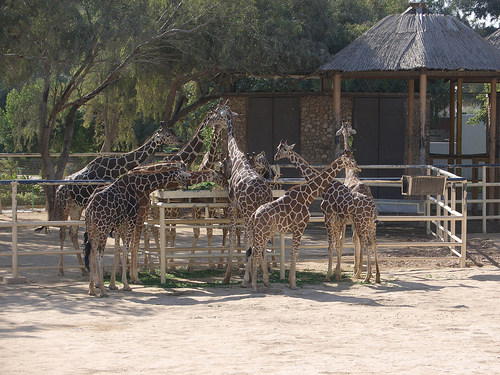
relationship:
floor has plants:
[22, 140, 480, 337] [69, 54, 231, 165]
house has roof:
[295, 15, 491, 175] [356, 7, 464, 71]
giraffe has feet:
[238, 148, 360, 292] [316, 269, 388, 286]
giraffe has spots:
[272, 140, 383, 285] [332, 198, 368, 220]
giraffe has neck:
[202, 98, 274, 289] [226, 129, 250, 170]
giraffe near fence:
[202, 98, 274, 289] [3, 132, 497, 279]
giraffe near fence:
[272, 138, 380, 286] [3, 132, 497, 279]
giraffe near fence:
[58, 104, 238, 299] [3, 132, 497, 279]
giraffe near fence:
[227, 138, 367, 294] [3, 132, 497, 279]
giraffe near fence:
[326, 111, 403, 292] [3, 132, 497, 279]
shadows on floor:
[1, 261, 441, 346] [0, 205, 499, 375]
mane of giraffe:
[158, 105, 217, 164] [99, 179, 165, 221]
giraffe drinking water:
[81, 159, 195, 297] [152, 171, 306, 216]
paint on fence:
[1, 157, 139, 189] [1, 152, 498, 284]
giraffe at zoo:
[238, 148, 360, 292] [2, 2, 496, 371]